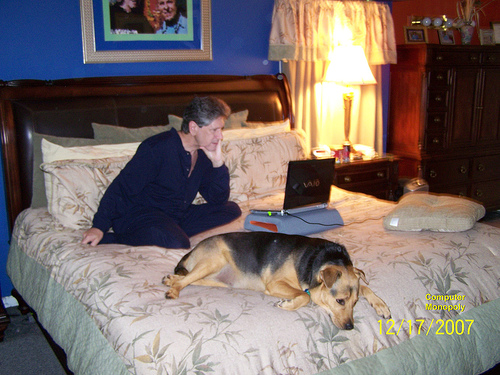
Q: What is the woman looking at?
A: Laptop.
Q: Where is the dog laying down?
A: Bed.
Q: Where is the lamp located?
A: Nightstand.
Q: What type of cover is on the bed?
A: Comforter.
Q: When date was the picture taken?
A: 12/17/2007.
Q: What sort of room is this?
A: Bedroom.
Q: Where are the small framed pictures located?
A: Armoire.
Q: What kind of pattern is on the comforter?
A: Floral.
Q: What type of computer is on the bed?
A: Laptop.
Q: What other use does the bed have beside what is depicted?
A: Sleep.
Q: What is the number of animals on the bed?
A: One.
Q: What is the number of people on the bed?
A: One.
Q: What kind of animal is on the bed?
A: Dog.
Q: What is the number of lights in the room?
A: One.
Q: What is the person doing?
A: Looking at their laptop.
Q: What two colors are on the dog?
A: Brown and black.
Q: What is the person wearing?
A: Pajamas.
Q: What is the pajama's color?
A: Blue.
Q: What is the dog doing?
A: Laying down.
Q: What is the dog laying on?
A: A bed.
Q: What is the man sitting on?
A: The bed.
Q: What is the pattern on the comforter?
A: Leaves.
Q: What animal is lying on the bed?
A: A dog.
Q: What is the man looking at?
A: A laptop.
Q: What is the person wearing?
A: Blue pajamas.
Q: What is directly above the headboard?
A: A framed picture.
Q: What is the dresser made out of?
A: Wood.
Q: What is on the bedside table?
A: A lamp.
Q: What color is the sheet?
A: White.